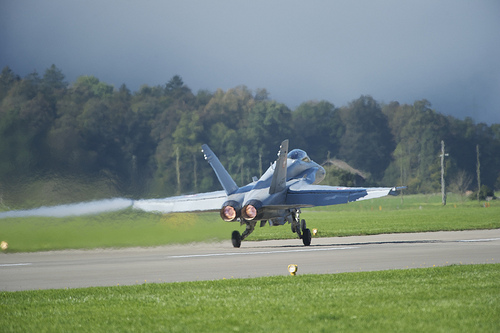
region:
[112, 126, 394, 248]
plane on runway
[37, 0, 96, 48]
white clouds in blue sky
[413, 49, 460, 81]
white clouds in blue sky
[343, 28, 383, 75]
white clouds in blue sky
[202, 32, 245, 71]
white clouds in blue sky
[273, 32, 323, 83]
white clouds in blue sky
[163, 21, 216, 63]
white clouds in blue sky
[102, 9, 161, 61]
white clouds in blue sky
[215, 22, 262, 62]
white clouds in blue sky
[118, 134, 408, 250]
a fighter taking off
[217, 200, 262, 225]
the rear two turbines of the fighter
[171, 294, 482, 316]
a lot of grass in the field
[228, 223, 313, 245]
the landing gear of the fighter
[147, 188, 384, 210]
the two wings of the fighter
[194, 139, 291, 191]
two vertical stabilizer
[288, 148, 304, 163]
the fighter cockpit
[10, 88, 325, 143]
a dense forest inn the bakcground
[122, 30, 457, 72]
the sky in the background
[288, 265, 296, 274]
a unrecognizable yellow object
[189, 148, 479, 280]
silver airplane getting ready to take off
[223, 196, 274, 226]
rear engines on plane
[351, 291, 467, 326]
green grass on side of road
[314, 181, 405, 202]
right wing on side of plane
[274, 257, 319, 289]
yellow light on side of grass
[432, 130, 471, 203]
wooden telephone poles in distance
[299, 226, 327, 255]
black front right tire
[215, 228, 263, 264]
left black tire on airplane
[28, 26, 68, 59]
dark blue patch of sky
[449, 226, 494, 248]
white painted line on ground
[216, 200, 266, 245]
jet engines on back of plane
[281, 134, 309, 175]
cockpit window of plane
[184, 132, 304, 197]
tail fins of plane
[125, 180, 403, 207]
wings of the plane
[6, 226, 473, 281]
asphalt runway beneath plane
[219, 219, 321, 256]
landing gear of the plane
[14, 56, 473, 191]
dense tree line behind plane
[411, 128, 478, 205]
wooden power pole near plane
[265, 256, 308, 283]
yellow light on runway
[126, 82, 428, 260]
silver jet plane on runway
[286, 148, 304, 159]
fighter jet cockpit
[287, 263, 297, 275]
runway light with yellow metal cover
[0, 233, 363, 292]
airport runway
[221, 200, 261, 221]
aircraft engines with afterburners engaged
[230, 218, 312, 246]
jet aircraft landing gear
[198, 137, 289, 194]
aircraft vertical stabilizers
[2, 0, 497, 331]
fighter jet taking off from rural airport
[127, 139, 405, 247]
military jet painted tactical gray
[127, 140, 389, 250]
military fighter jet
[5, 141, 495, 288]
fighter jet nosing up for takeoff